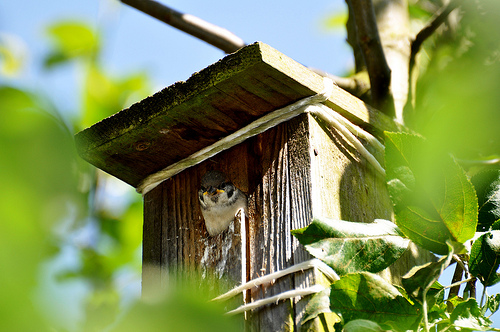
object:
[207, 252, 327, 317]
rope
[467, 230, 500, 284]
leaf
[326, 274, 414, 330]
leaf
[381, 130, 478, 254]
leaf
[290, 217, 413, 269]
leaf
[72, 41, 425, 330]
bird house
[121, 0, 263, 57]
branch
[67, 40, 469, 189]
roof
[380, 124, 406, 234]
edge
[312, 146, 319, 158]
nail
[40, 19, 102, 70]
leaf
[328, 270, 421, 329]
leaf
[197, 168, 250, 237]
bird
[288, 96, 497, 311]
leaves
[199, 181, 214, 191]
eyes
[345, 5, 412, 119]
tree trunk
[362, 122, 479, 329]
leaves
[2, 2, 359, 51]
sky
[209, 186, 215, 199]
beak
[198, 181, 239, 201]
markings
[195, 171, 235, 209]
head